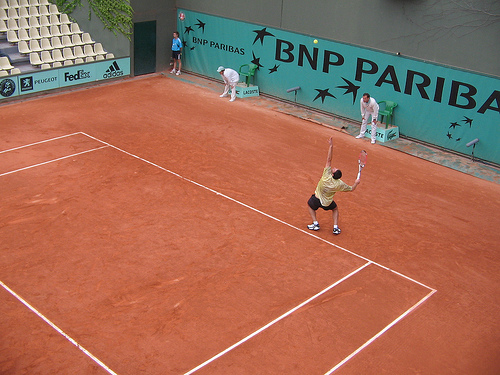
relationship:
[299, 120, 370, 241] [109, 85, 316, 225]
man on court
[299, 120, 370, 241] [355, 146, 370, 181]
man has racket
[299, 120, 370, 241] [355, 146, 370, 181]
man holding racket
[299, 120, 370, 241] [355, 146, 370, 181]
man swinging racket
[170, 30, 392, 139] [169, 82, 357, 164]
people on side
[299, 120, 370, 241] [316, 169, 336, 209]
man has shirt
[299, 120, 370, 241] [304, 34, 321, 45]
man hitting ball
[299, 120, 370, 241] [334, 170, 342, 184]
man has hair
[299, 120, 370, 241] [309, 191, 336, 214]
man wearing shorts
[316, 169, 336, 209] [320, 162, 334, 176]
shirt has sleeves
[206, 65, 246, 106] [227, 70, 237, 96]
man wearing white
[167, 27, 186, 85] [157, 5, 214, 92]
person in corner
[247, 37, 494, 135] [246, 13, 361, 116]
sign on wall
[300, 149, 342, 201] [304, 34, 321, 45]
player serving ball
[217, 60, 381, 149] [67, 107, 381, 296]
umpires watching match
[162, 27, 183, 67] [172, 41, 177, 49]
boy in blue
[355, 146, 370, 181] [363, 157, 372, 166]
racket has red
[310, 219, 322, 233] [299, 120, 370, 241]
shoe on man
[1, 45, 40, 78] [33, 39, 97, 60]
stairs by chairs